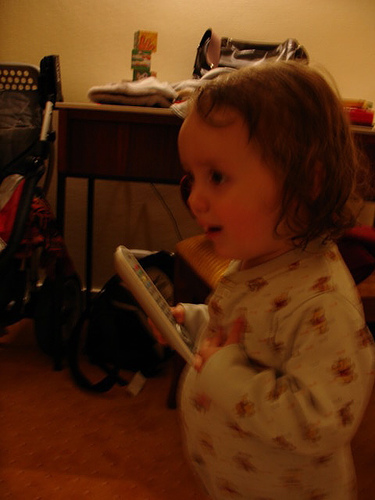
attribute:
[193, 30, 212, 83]
strap — brown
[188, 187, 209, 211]
nose — child's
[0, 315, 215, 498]
flooring — carpeted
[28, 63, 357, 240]
table — brown, wooden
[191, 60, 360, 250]
hair — brown, brunette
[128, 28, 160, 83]
blocks — stacked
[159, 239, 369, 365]
shirt — long sleeved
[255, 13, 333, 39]
wall — white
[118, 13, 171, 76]
blocks — stacked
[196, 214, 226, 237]
mouth — open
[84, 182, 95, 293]
legs — black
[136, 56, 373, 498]
child — small, facing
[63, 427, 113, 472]
ground — brown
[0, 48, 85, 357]
stroller — folded-up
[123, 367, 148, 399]
tag — white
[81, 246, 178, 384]
bag — black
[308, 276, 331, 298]
design — red